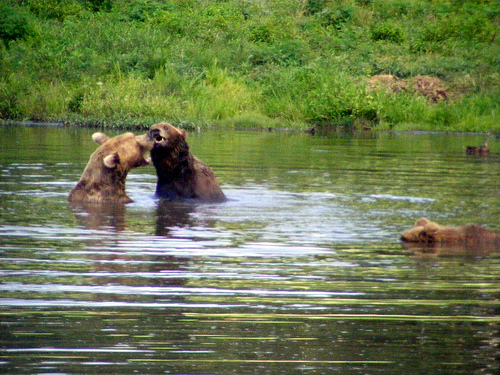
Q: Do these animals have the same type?
A: Yes, all the animals are bears.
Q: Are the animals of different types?
A: No, all the animals are bears.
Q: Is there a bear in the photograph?
A: Yes, there is a bear.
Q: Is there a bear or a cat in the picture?
A: Yes, there is a bear.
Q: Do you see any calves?
A: No, there are no calves.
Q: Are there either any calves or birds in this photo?
A: No, there are no calves or birds.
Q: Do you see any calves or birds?
A: No, there are no calves or birds.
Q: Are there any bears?
A: Yes, there is a bear.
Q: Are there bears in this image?
A: Yes, there is a bear.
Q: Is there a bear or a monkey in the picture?
A: Yes, there is a bear.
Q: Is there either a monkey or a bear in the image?
A: Yes, there is a bear.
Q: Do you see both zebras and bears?
A: No, there is a bear but no zebras.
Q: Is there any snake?
A: No, there are no snakes.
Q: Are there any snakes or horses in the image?
A: No, there are no snakes or horses.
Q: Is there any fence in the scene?
A: No, there are no fences.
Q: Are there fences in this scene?
A: No, there are no fences.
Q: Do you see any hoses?
A: No, there are no hoses.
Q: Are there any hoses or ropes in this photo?
A: No, there are no hoses or ropes.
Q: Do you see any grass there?
A: Yes, there is grass.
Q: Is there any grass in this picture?
A: Yes, there is grass.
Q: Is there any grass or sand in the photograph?
A: Yes, there is grass.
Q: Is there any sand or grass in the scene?
A: Yes, there is grass.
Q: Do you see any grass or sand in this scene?
A: Yes, there is grass.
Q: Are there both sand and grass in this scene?
A: No, there is grass but no sand.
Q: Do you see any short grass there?
A: Yes, there is short grass.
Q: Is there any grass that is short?
A: Yes, there is grass that is short.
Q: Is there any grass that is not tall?
A: Yes, there is short grass.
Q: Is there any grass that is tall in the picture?
A: Yes, there is tall grass.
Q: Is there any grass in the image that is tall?
A: Yes, there is grass that is tall.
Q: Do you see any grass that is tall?
A: Yes, there is grass that is tall.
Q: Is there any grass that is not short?
A: Yes, there is tall grass.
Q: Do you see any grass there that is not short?
A: Yes, there is tall grass.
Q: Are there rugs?
A: No, there are no rugs.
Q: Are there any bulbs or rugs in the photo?
A: No, there are no rugs or bulbs.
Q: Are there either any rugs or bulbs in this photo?
A: No, there are no rugs or bulbs.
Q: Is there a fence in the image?
A: No, there are no fences.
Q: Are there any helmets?
A: No, there are no helmets.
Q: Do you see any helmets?
A: No, there are no helmets.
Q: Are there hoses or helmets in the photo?
A: No, there are no helmets or hoses.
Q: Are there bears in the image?
A: Yes, there is a bear.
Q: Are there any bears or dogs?
A: Yes, there is a bear.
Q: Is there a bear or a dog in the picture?
A: Yes, there is a bear.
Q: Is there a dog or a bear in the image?
A: Yes, there is a bear.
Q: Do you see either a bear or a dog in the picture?
A: Yes, there is a bear.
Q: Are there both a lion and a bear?
A: No, there is a bear but no lions.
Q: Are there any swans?
A: No, there are no swans.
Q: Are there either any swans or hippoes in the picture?
A: No, there are no swans or hippoes.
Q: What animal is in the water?
A: The bear is in the water.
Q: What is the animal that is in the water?
A: The animal is a bear.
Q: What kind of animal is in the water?
A: The animal is a bear.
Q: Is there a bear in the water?
A: Yes, there is a bear in the water.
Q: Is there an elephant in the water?
A: No, there is a bear in the water.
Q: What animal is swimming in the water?
A: The bear is swimming in the water.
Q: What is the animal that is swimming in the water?
A: The animal is a bear.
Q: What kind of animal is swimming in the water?
A: The animal is a bear.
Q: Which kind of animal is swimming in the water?
A: The animal is a bear.